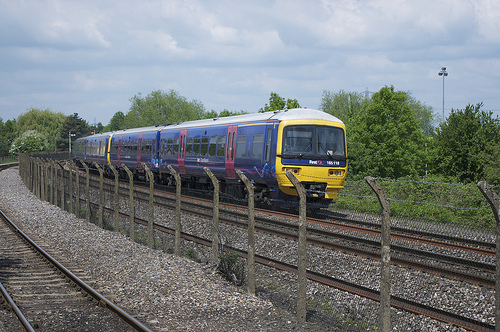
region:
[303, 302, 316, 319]
bottom of a fence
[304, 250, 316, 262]
part of a fence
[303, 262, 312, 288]
edge of a pole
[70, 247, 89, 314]
part of a rail way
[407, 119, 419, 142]
edge of a bush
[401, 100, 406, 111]
branches of a bush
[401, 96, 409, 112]
leaves of a tree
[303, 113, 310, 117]
part of a train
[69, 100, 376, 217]
Some Subway Transport Cars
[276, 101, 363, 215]
Yellow Subway Car Front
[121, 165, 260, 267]
Some Protective Chain Link Fencing with barbwire overhang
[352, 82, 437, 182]
Green Trees in the background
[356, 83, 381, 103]
Large Electrical A Frame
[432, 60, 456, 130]
An Electrical Light Pole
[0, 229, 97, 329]
Some Rail Tracks laid out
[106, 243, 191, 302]
Some Gravel stones lining the tracks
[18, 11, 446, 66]
Lightly cloudy Skies above the Subway Cars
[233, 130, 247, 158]
A subway Car Seat Window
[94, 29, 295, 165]
the sky is white and blue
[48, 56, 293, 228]
the sky is white and blue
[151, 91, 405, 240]
the train is yellow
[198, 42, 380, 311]
the train is yellow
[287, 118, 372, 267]
the train is yellow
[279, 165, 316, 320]
Support post for safety fence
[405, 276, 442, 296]
Chain-link safety fence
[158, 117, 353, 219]
Lead car of passenger train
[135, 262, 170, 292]
Gravel fill for railway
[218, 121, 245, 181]
Access doors for passenger train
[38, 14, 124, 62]
White clouds in a partly cloudy sky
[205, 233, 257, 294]
Weeds growing along fence line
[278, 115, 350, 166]
Windshield of the passenger train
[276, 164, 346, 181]
Headlights of passenger train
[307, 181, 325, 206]
Mechanism to hook the trains together